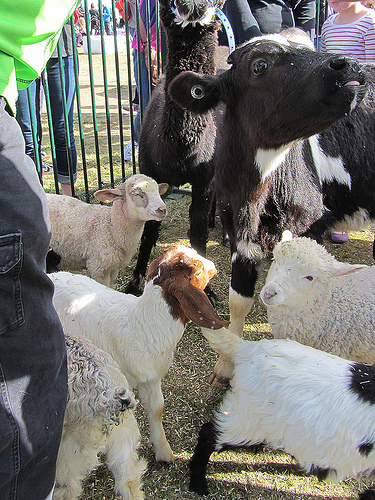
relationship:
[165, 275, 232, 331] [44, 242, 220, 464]
brown ear on goat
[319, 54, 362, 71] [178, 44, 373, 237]
nose on a calf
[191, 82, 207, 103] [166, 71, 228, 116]
tag on a ear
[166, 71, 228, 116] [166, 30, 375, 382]
ear on a animals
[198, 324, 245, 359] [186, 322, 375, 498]
tail on a animal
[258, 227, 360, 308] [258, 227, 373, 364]
head on a animal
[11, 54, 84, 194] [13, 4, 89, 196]
jeans on a woman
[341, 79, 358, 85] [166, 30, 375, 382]
tongue on a animals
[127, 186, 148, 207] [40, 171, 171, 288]
patch on a lamb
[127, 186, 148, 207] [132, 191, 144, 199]
patch around an eye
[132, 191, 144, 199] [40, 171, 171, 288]
eye on a lamb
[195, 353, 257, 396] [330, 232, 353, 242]
foot in a shoe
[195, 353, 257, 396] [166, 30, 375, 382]
foot under a animals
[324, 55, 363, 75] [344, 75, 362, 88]
nose under a tounge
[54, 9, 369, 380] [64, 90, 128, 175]
animals has a a shadows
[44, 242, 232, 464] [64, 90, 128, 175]
goat has a a shadows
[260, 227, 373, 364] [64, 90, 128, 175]
animal has a a shadows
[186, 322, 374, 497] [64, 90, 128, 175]
animal has a a shadows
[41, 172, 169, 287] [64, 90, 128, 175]
animal has a a shadows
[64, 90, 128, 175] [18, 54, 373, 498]
shadows on a ground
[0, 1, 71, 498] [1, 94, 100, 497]
person wearing jeans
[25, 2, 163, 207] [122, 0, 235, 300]
gate keep animals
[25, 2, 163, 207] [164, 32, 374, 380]
gate keep animals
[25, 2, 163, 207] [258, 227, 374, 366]
gate keep animals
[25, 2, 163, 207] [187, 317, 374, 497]
gate keep animals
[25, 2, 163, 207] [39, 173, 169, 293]
gate keep animals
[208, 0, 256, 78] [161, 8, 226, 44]
tag around neck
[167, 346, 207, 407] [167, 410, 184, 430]
ground with leaves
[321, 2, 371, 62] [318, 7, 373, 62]
child wearing shirt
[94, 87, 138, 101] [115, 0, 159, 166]
shadows of people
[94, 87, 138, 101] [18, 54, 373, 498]
shadows on ground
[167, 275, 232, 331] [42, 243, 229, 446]
brown ear on goat.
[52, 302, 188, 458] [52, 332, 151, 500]
fur of goat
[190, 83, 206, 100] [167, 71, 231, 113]
tag in ear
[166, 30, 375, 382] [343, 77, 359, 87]
animals with tongue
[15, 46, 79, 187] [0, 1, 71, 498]
jeans on person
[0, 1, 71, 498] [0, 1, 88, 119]
person in shirt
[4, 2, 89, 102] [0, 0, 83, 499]
shirt on person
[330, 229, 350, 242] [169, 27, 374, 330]
shoe under cow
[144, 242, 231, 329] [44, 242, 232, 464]
head of goat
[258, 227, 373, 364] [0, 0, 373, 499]
animal in zoo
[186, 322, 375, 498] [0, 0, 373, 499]
animal in zoo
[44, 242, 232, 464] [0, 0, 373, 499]
goat in zoo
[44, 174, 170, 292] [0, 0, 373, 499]
animal in zoo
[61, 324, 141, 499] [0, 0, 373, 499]
goat in zoo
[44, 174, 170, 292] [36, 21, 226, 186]
animal in pen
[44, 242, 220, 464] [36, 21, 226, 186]
goat in pen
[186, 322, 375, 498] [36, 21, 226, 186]
animal in pen